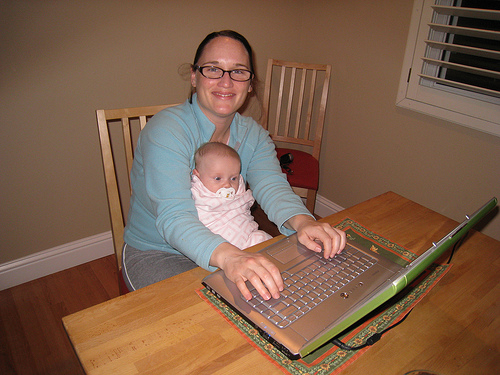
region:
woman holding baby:
[127, 23, 351, 297]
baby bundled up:
[190, 140, 281, 258]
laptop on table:
[205, 195, 495, 360]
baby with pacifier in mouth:
[190, 137, 270, 247]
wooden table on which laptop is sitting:
[52, 186, 497, 371]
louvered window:
[392, 27, 497, 132]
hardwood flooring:
[0, 251, 115, 371]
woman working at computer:
[121, 25, 351, 305]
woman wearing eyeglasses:
[117, 26, 347, 296]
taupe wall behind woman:
[6, 1, 87, 227]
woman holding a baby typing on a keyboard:
[107, 26, 489, 371]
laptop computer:
[197, 191, 498, 371]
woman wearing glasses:
[118, 16, 353, 318]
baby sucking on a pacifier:
[184, 129, 283, 260]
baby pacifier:
[214, 184, 241, 204]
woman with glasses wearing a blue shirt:
[177, 24, 267, 153]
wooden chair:
[236, 41, 343, 220]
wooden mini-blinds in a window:
[382, 0, 497, 147]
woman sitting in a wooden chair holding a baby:
[89, 13, 347, 300]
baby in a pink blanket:
[178, 133, 284, 263]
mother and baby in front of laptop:
[151, 30, 396, 318]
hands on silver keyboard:
[148, 206, 374, 313]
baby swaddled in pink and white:
[186, 130, 278, 259]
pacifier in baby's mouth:
[175, 131, 260, 228]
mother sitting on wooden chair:
[95, 19, 307, 271]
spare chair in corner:
[259, 23, 336, 212]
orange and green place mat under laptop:
[173, 198, 465, 372]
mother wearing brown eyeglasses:
[156, 21, 281, 111]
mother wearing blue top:
[96, 21, 336, 278]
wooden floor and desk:
[31, 242, 275, 364]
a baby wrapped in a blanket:
[181, 136, 293, 288]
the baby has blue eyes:
[188, 141, 271, 208]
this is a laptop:
[228, 153, 473, 360]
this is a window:
[401, 37, 488, 114]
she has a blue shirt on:
[118, 87, 196, 272]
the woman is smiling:
[179, 34, 308, 181]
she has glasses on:
[185, 41, 354, 166]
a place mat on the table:
[192, 283, 289, 373]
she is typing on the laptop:
[181, 203, 456, 283]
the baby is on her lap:
[143, 31, 370, 298]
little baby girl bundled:
[184, 142, 270, 232]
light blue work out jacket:
[149, 113, 325, 255]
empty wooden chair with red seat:
[260, 39, 372, 191]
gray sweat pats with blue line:
[106, 224, 235, 329]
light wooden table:
[117, 307, 244, 353]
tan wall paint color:
[21, 109, 84, 158]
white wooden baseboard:
[31, 251, 88, 271]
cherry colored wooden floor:
[23, 287, 74, 312]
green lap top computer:
[217, 239, 451, 362]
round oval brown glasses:
[189, 58, 297, 106]